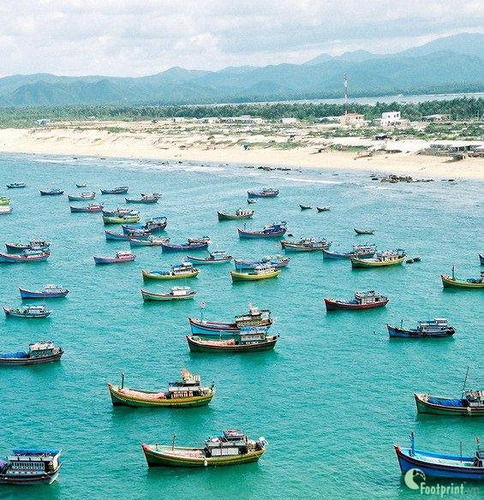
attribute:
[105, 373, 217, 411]
boat — yellow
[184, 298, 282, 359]
boats — anchored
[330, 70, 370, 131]
tower — red, white, signal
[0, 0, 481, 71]
sky — cloudy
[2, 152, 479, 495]
water — shallow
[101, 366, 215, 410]
boat — group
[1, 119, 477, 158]
sand/beach — beach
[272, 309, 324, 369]
water — body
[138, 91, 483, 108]
water — body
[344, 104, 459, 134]
buildings — three, low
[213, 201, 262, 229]
boat — brown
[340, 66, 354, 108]
pole — tall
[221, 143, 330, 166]
sand — white